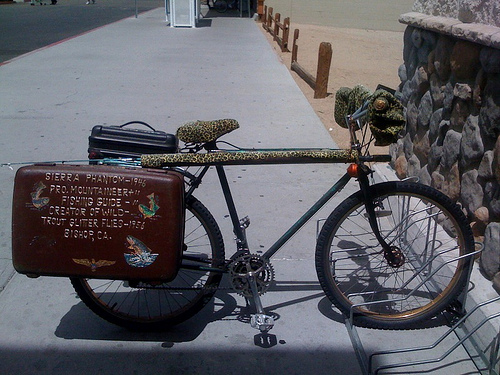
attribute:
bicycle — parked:
[64, 98, 470, 330]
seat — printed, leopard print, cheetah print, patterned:
[177, 119, 239, 145]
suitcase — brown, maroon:
[11, 163, 184, 286]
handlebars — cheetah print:
[338, 84, 403, 120]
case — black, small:
[87, 125, 178, 159]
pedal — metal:
[252, 313, 277, 334]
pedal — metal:
[238, 216, 251, 229]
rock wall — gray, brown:
[412, 44, 500, 170]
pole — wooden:
[316, 43, 334, 100]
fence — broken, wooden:
[288, 28, 335, 102]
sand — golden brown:
[317, 15, 399, 43]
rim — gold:
[360, 306, 422, 320]